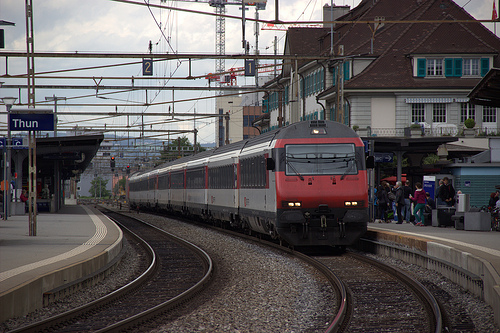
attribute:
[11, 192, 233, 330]
track — metallic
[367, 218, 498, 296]
walkway — gray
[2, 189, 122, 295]
tarmac — gray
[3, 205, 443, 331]
tracks — rusty, old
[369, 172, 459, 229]
people — in the picture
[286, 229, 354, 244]
black — in the picture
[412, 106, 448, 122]
window — striped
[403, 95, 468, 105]
awning — small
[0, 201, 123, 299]
tarmac — gray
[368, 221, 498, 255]
tarmac — gray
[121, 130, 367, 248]
train — tall, red, grey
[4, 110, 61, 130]
sign — blue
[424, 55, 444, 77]
window — small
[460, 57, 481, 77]
window — small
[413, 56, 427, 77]
shutters — blue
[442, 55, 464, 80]
shutters — blue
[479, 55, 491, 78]
shutters — blue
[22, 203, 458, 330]
train track — metalic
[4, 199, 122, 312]
tarmac — gray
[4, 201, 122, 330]
walkway — gray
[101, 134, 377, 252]
train — red, black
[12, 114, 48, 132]
word — thun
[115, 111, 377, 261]
car — red, train car, silver